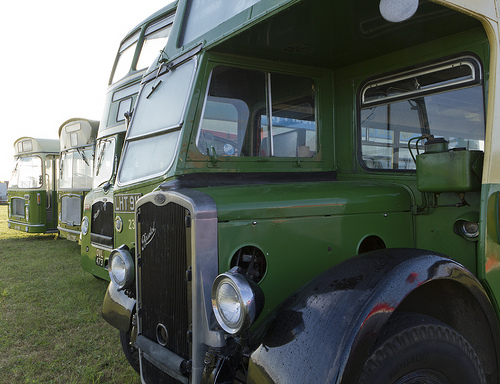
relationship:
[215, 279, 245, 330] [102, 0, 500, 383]
light on front of bus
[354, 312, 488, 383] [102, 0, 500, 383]
tire on bus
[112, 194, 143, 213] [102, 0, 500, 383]
plate on bus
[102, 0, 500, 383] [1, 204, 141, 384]
bus on grass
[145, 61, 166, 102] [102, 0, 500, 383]
wiper on bus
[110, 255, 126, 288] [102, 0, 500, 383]
light on bus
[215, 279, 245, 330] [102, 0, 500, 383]
light on bus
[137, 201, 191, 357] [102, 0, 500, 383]
grill of bus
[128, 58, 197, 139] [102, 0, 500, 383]
windshield of bus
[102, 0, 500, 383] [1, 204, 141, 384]
bus parked in grass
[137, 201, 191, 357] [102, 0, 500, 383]
grill on bus